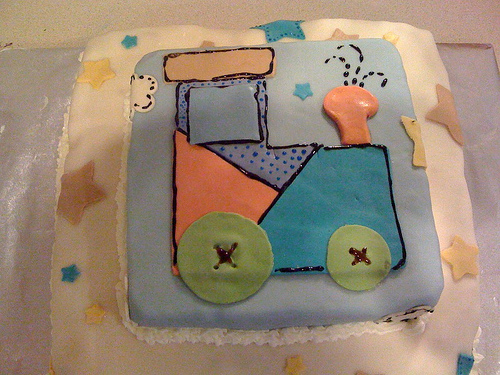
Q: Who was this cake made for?
A: A baby.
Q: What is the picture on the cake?
A: A train.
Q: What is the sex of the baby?
A: Boy.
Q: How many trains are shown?
A: One.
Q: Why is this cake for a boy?
A: Boys like trains.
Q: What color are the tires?
A: Green.